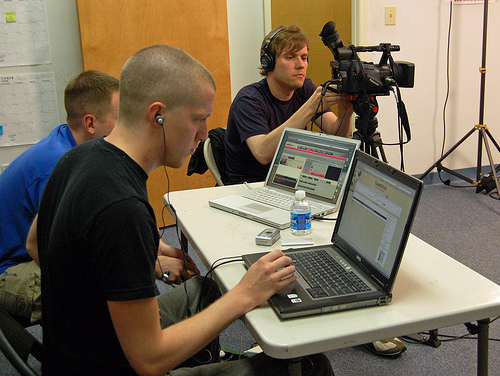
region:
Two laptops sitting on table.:
[228, 112, 430, 339]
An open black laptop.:
[273, 140, 428, 307]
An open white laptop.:
[220, 115, 365, 236]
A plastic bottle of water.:
[281, 175, 323, 242]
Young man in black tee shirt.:
[23, 35, 215, 372]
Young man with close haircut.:
[117, 27, 219, 169]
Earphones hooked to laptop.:
[137, 89, 199, 174]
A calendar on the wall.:
[2, 65, 62, 148]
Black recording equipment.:
[319, 13, 412, 132]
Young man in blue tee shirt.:
[5, 75, 120, 272]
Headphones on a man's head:
[256, 23, 311, 76]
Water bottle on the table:
[292, 186, 311, 248]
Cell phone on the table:
[251, 221, 281, 248]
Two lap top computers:
[201, 123, 428, 325]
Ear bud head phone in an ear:
[150, 107, 170, 129]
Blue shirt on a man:
[1, 119, 83, 286]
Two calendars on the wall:
[1, 0, 66, 150]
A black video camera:
[315, 13, 417, 192]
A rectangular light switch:
[383, 3, 398, 27]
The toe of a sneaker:
[359, 333, 416, 362]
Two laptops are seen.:
[223, 133, 452, 312]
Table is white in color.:
[419, 270, 484, 311]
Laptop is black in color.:
[281, 244, 350, 304]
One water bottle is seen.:
[290, 189, 328, 234]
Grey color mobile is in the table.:
[247, 218, 279, 245]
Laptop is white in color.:
[248, 134, 312, 224]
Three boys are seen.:
[38, 26, 301, 178]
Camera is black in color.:
[319, 28, 411, 123]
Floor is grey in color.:
[436, 197, 491, 245]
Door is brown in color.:
[86, 16, 208, 51]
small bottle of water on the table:
[282, 186, 313, 241]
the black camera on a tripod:
[308, 16, 428, 161]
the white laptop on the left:
[192, 118, 357, 235]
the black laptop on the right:
[242, 152, 431, 328]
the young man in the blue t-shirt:
[5, 56, 126, 271]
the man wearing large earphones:
[222, 9, 329, 180]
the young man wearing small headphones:
[26, 40, 291, 366]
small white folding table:
[156, 158, 498, 365]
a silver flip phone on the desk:
[244, 222, 284, 249]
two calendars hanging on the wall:
[2, 3, 71, 148]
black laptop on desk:
[236, 132, 431, 319]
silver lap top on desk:
[205, 115, 381, 248]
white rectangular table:
[164, 135, 499, 367]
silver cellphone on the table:
[245, 224, 284, 252]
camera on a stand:
[300, 11, 435, 168]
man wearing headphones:
[247, 15, 323, 105]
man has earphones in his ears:
[25, 36, 263, 374]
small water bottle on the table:
[282, 184, 330, 254]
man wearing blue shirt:
[0, 55, 164, 284]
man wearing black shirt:
[9, 42, 240, 374]